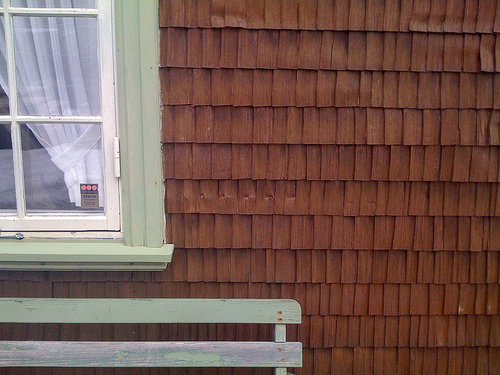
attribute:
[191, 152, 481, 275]
wall — wood, brown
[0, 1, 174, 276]
window — closed, painted, white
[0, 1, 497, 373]
wall — brown, wood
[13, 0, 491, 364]
brown wall — wood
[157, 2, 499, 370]
wall — BROWN, wood, in the picture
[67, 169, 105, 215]
sign — silver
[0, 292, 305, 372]
bench — weather beaten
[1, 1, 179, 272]
window frame — washed, green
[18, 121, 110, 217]
glass — clear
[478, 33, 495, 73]
shingle — loose, brown, hanging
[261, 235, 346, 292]
blocks — in the picture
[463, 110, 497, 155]
wall blocks — in the picture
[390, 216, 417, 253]
wall blocks — in the picture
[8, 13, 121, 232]
window — closed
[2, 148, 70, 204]
spread — white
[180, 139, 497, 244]
shingles — brown